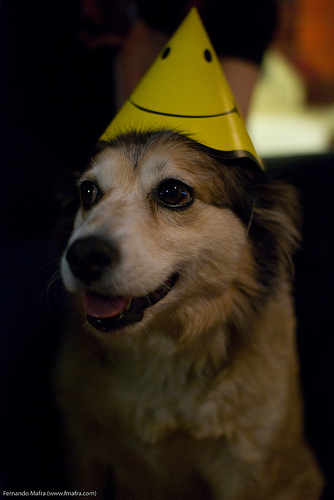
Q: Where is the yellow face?
A: On the hat.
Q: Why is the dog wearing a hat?
A: Birthday.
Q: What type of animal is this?
A: A dog.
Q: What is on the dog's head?
A: A hat.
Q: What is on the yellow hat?
A: A smiley face.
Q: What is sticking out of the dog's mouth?
A: His tongue.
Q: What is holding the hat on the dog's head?
A: A string.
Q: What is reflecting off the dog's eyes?
A: Lights.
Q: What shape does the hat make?
A: A triangle.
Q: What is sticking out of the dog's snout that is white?
A: Whiskers.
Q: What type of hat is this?
A: A party hat.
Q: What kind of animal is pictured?
A: A dog.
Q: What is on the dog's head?
A: A hat.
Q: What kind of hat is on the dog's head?
A: Smiley face hat.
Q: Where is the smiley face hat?
A: On the dog.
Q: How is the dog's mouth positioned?
A: Open.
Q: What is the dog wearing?
A: A party hat.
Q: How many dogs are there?
A: One.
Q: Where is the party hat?
A: Dog's head.